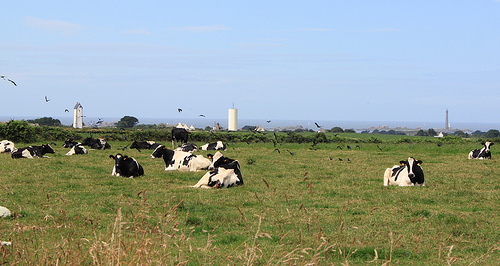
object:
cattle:
[184, 152, 246, 188]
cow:
[382, 155, 427, 186]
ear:
[399, 161, 406, 166]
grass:
[0, 143, 499, 266]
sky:
[0, 0, 499, 124]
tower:
[227, 103, 239, 132]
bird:
[43, 95, 50, 103]